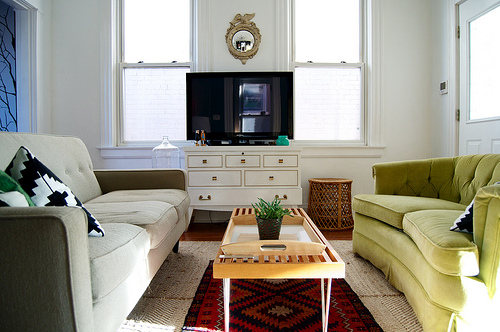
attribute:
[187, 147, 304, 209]
dresser — white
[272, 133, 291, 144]
jar — small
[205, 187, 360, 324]
table — small, wicker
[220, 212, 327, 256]
tray — wooden